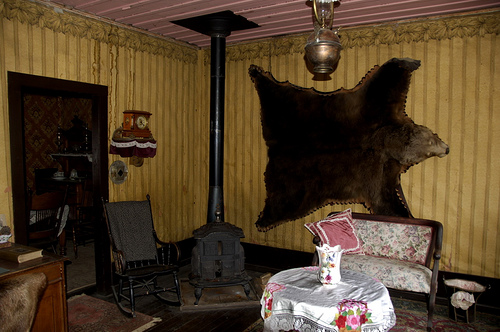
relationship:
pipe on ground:
[204, 19, 231, 225] [152, 225, 288, 321]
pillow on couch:
[300, 208, 364, 259] [312, 210, 443, 332]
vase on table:
[313, 242, 343, 286] [250, 264, 404, 331]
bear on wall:
[248, 56, 451, 233] [221, 42, 499, 271]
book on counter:
[4, 238, 47, 267] [1, 254, 71, 330]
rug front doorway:
[66, 287, 164, 327] [4, 64, 116, 293]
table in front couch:
[256, 266, 395, 330] [312, 210, 443, 332]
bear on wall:
[238, 65, 432, 205] [435, 69, 472, 134]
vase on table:
[313, 242, 343, 286] [264, 274, 388, 321]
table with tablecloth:
[260, 265, 390, 330] [258, 265, 395, 332]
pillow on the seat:
[315, 221, 362, 243] [382, 257, 399, 280]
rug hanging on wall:
[66, 291, 164, 332] [429, 59, 464, 121]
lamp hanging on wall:
[301, 0, 343, 75] [161, 71, 188, 113]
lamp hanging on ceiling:
[301, 0, 343, 75] [262, 0, 294, 20]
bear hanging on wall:
[248, 56, 451, 233] [442, 72, 472, 132]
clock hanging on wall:
[116, 108, 154, 154] [154, 79, 180, 129]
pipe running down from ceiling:
[204, 29, 231, 227] [201, 10, 278, 28]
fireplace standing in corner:
[188, 192, 259, 306] [176, 40, 260, 270]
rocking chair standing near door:
[96, 190, 185, 322] [22, 93, 96, 297]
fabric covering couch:
[340, 217, 439, 295] [312, 209, 443, 330]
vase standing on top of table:
[313, 240, 343, 286] [258, 262, 397, 330]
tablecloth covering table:
[258, 262, 397, 329] [260, 265, 390, 330]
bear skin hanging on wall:
[247, 56, 448, 234] [201, 12, 484, 310]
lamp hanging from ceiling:
[301, 0, 343, 75] [50, 1, 483, 48]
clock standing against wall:
[120, 109, 153, 138] [2, 0, 203, 294]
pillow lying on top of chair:
[300, 208, 364, 259] [310, 209, 445, 330]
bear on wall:
[248, 56, 451, 233] [197, 37, 482, 286]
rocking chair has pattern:
[97, 192, 183, 321] [365, 229, 409, 257]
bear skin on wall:
[239, 49, 448, 240] [197, 37, 482, 286]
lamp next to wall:
[106, 100, 164, 188] [3, 15, 200, 252]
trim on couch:
[347, 211, 440, 231] [312, 210, 443, 332]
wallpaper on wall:
[2, 9, 210, 257] [0, 12, 206, 264]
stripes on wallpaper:
[157, 57, 198, 240] [2, 9, 210, 257]